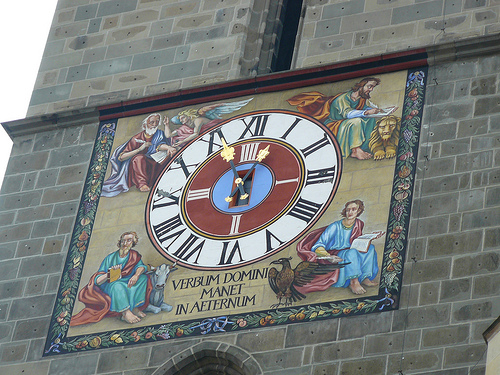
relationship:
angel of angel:
[162, 96, 254, 148] [152, 117, 232, 153]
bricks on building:
[51, 23, 232, 97] [69, 10, 213, 136]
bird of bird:
[263, 255, 353, 311] [250, 246, 353, 283]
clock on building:
[144, 107, 342, 271] [69, 10, 213, 136]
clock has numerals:
[144, 107, 342, 271] [205, 117, 364, 187]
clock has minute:
[144, 107, 342, 271] [207, 134, 269, 222]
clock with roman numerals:
[144, 107, 342, 271] [151, 115, 335, 264]